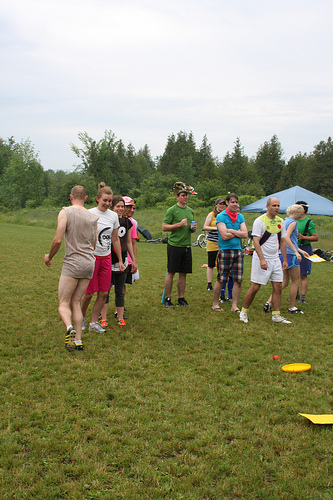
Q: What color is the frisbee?
A: Yellow.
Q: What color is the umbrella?
A: Blue.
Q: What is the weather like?
A: Cloudy.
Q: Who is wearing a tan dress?
A: Man on left.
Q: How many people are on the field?
A: 10.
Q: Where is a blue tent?
A: Behind people on right.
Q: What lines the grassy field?
A: Line of trees.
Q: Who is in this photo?
A: Men and women.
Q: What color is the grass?
A: Green.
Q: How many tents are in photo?
A: One.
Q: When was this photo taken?
A: In the daytime.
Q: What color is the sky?
A: Blue.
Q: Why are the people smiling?
A: Having fun.